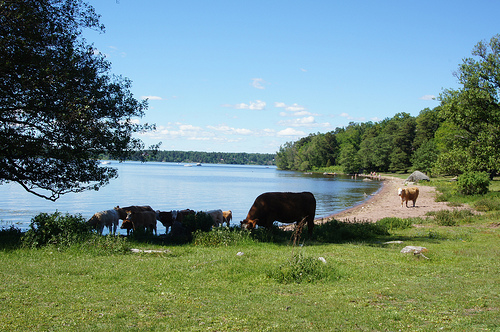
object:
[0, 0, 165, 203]
tree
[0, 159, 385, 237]
water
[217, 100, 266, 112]
clouds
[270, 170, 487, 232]
sand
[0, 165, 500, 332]
grass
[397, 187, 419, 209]
cow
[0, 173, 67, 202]
branch